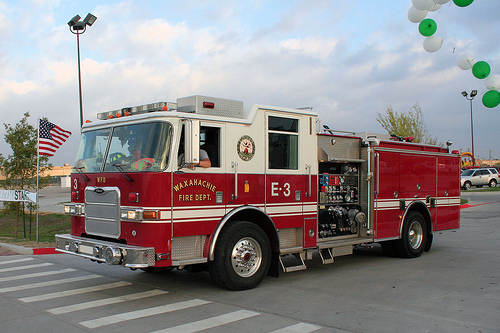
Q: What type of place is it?
A: It is a street.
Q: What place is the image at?
A: It is at the street.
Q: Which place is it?
A: It is a street.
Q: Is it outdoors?
A: Yes, it is outdoors.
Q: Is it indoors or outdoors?
A: It is outdoors.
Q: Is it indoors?
A: No, it is outdoors.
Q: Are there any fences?
A: No, there are no fences.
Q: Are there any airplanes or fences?
A: No, there are no fences or airplanes.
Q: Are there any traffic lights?
A: No, there are no traffic lights.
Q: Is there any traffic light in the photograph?
A: No, there are no traffic lights.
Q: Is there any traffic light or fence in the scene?
A: No, there are no traffic lights or fences.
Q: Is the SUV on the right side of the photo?
A: Yes, the SUV is on the right of the image.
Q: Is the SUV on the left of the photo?
A: No, the SUV is on the right of the image.